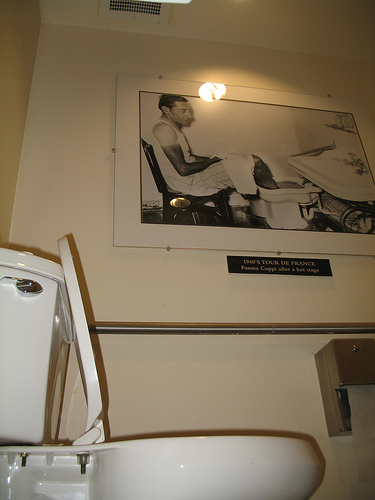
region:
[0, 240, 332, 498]
a white porcelain toilet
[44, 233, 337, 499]
a toilet with the seat up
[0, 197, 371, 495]
a toilet in a public restroom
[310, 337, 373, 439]
a locked toilet paper dispenser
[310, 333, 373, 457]
a locked roll of toilet paper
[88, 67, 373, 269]
an old photograph on the wall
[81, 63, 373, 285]
a poster of an image from the 1940s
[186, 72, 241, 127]
reflection of the light on glass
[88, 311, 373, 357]
a metal railing in a restroom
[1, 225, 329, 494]
white and brown toilet with seat and tank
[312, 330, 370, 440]
wood shelf attached to the wall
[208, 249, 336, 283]
black identification placard under wall art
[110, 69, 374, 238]
athlete soaking his feet while sitting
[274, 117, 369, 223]
white sink in wall mounted photo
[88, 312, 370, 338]
dark colored wainscoting on a tan wall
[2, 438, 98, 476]
bolts holding toilet tank and toilet seat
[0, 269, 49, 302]
chrome toilet flusher handle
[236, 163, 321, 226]
white foot soaker in wall photograph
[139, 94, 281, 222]
athlete sits in black chair soaking feet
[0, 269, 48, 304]
chrome handle on a toilet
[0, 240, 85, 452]
white toilet tank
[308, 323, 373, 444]
toilet paper dispenser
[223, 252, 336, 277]
small black sign on the wall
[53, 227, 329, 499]
toilet with an open lid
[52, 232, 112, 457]
white toilet lid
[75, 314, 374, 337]
round metal bar on the wall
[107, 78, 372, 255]
poster on the wall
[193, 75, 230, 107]
reflection of a light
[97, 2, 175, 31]
vent on the ceiling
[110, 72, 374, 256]
picture of a man hanging in the wall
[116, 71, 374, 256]
picture of a man with his feets on toilet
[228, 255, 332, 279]
black signboard with golden letters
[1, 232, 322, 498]
white clean toilet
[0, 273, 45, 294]
small gray metal lever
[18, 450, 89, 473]
small gray metal screws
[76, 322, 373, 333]
gray metal pole in the wall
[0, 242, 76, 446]
white sump tank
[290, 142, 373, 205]
white handwash in the picture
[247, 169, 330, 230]
white toilet in the picture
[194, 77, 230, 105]
reflection of light onto picture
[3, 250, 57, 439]
white tank on toilet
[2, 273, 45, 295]
silver handle on toilet tank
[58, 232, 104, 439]
toilet seat is up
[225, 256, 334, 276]
black sign under picture on wall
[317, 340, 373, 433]
brown toilet paper holder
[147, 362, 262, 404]
wall is off-white in color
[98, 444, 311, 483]
toilet bowl is white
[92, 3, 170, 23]
air filter in ceiling of bathroom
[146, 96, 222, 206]
man sitting on chair in picture on wall